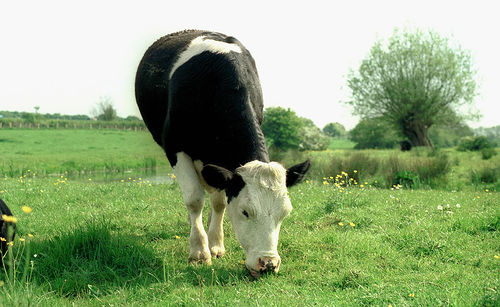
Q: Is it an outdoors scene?
A: Yes, it is outdoors.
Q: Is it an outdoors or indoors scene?
A: It is outdoors.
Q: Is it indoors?
A: No, it is outdoors.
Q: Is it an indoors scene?
A: No, it is outdoors.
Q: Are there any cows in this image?
A: Yes, there is a cow.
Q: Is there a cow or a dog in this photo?
A: Yes, there is a cow.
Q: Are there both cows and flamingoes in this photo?
A: No, there is a cow but no flamingoes.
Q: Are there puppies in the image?
A: No, there are no puppies.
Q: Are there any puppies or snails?
A: No, there are no puppies or snails.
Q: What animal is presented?
A: The animal is a cow.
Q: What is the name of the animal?
A: The animal is a cow.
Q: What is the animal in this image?
A: The animal is a cow.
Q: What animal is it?
A: The animal is a cow.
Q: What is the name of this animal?
A: This is a cow.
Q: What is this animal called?
A: This is a cow.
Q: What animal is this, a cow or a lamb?
A: This is a cow.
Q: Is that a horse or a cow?
A: That is a cow.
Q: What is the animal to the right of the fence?
A: The animal is a cow.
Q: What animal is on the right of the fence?
A: The animal is a cow.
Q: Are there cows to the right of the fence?
A: Yes, there is a cow to the right of the fence.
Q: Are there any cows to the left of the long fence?
A: No, the cow is to the right of the fence.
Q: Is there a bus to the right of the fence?
A: No, there is a cow to the right of the fence.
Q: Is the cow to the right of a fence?
A: Yes, the cow is to the right of a fence.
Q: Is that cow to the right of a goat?
A: No, the cow is to the right of a fence.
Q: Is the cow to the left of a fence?
A: No, the cow is to the right of a fence.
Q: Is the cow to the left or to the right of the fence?
A: The cow is to the right of the fence.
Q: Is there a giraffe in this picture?
A: No, there are no giraffes.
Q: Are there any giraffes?
A: No, there are no giraffes.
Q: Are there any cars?
A: No, there are no cars.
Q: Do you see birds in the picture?
A: No, there are no birds.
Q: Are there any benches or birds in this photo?
A: No, there are no birds or benches.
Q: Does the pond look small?
A: Yes, the pond is small.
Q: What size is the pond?
A: The pond is small.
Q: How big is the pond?
A: The pond is small.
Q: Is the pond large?
A: No, the pond is small.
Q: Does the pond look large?
A: No, the pond is small.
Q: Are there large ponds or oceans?
A: No, there is a pond but it is small.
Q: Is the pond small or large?
A: The pond is small.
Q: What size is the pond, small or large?
A: The pond is small.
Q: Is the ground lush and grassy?
A: Yes, the ground is lush and grassy.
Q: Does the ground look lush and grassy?
A: Yes, the ground is lush and grassy.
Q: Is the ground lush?
A: Yes, the ground is lush.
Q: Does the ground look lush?
A: Yes, the ground is lush.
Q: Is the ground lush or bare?
A: The ground is lush.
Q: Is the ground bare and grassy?
A: No, the ground is grassy but lush.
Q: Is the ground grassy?
A: Yes, the ground is grassy.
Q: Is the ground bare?
A: No, the ground is grassy.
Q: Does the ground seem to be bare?
A: No, the ground is grassy.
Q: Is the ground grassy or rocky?
A: The ground is grassy.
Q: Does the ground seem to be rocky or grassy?
A: The ground is grassy.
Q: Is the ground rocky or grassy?
A: The ground is grassy.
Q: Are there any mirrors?
A: No, there are no mirrors.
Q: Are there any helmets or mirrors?
A: No, there are no mirrors or helmets.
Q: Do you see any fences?
A: Yes, there is a fence.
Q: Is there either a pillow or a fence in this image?
A: Yes, there is a fence.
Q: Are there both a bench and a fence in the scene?
A: No, there is a fence but no benches.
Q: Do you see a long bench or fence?
A: Yes, there is a long fence.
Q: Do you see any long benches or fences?
A: Yes, there is a long fence.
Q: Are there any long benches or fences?
A: Yes, there is a long fence.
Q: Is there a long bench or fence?
A: Yes, there is a long fence.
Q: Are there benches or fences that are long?
A: Yes, the fence is long.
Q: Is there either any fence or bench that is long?
A: Yes, the fence is long.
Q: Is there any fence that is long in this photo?
A: Yes, there is a long fence.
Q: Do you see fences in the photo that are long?
A: Yes, there is a fence that is long.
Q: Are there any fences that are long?
A: Yes, there is a fence that is long.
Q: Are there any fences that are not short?
A: Yes, there is a long fence.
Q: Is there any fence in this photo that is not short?
A: Yes, there is a long fence.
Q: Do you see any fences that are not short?
A: Yes, there is a long fence.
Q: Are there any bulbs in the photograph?
A: No, there are no bulbs.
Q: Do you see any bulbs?
A: No, there are no bulbs.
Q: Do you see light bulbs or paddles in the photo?
A: No, there are no light bulbs or paddles.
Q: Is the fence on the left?
A: Yes, the fence is on the left of the image.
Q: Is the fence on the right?
A: No, the fence is on the left of the image.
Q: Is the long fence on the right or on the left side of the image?
A: The fence is on the left of the image.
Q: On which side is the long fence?
A: The fence is on the left of the image.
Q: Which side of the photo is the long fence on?
A: The fence is on the left of the image.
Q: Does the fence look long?
A: Yes, the fence is long.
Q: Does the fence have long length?
A: Yes, the fence is long.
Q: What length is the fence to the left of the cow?
A: The fence is long.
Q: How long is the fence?
A: The fence is long.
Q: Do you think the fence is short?
A: No, the fence is long.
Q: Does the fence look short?
A: No, the fence is long.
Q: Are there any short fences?
A: No, there is a fence but it is long.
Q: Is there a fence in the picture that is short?
A: No, there is a fence but it is long.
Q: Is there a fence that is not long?
A: No, there is a fence but it is long.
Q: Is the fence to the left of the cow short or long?
A: The fence is long.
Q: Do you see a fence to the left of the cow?
A: Yes, there is a fence to the left of the cow.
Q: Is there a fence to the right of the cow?
A: No, the fence is to the left of the cow.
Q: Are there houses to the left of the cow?
A: No, there is a fence to the left of the cow.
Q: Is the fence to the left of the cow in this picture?
A: Yes, the fence is to the left of the cow.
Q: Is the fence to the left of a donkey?
A: No, the fence is to the left of the cow.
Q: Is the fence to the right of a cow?
A: No, the fence is to the left of a cow.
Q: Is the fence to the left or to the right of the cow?
A: The fence is to the left of the cow.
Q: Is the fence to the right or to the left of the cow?
A: The fence is to the left of the cow.